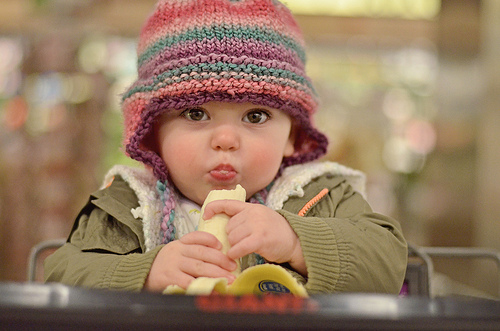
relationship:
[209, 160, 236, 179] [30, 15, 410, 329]
lips on chld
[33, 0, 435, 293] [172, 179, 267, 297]
child holding banana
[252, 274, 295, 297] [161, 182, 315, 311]
sticker on banana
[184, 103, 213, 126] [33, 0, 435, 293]
eye on child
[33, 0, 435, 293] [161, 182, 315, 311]
child eating banana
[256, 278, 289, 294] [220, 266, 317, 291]
sticker on peel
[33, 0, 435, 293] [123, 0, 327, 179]
child wearing purple beanie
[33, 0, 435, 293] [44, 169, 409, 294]
child wearing jacket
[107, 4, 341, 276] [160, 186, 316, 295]
child holding banana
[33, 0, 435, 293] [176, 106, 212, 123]
child has eye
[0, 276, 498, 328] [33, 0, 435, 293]
bar in front of child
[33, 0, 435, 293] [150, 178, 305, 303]
child eating banana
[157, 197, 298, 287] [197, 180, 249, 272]
hands holding banana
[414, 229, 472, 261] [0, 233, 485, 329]
bar on cart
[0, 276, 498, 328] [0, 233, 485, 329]
bar on cart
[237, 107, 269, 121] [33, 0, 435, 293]
eye on child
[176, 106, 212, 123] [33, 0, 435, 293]
eye on child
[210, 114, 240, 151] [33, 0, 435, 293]
nose on child